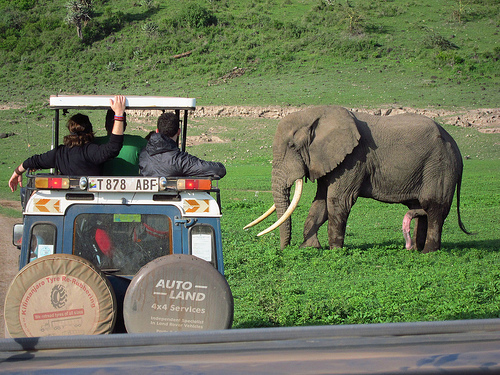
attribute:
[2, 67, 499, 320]
grass — green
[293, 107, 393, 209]
ear — wide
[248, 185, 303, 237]
tusks — big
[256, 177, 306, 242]
tusks — white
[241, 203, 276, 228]
tusks — white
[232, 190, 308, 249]
tusks — pointy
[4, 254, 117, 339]
wheel — covered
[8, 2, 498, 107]
hill — grassy, green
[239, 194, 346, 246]
tusks — ivory 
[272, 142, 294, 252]
trunk — long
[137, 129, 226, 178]
windbreaker — black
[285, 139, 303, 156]
eye — open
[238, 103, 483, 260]
elephant — grey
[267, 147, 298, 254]
trunk — long, grey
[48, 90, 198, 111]
top — white